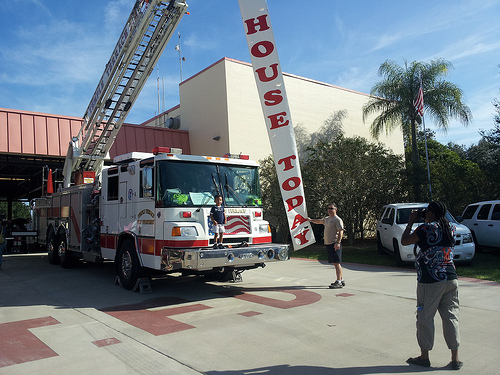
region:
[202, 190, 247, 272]
little boy standing on a truck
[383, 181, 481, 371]
a woman taking a picture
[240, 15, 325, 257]
a large white and red sign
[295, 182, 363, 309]
a man standing by the sign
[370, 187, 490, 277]
a white parked car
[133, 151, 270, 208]
the windshield of a truck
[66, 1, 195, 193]
ladder coming out of the truck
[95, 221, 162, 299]
a tire secured in place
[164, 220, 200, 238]
headlight on a truck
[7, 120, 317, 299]
a red and white firetruck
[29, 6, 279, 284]
a white and red fire hydrant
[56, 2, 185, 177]
a retractable fire ladder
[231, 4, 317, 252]
sign that reads HOUSE TODAY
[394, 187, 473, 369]
a woman taking photograph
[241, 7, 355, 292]
man holding large sign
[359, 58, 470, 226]
a large palm tree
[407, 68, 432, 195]
a waving American flag on pole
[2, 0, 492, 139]
a cloudy blue sky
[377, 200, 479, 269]
a parked white SUV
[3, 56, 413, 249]
large fire house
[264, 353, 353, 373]
shadow on the ground.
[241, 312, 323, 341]
driveway made of concrete.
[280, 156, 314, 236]
red lettering on sign.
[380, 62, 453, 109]
leaves on the tree.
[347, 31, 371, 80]
clouds in the sky.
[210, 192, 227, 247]
kid standing on truck.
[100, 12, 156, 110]
ladder on the truck.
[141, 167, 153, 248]
door of the truck.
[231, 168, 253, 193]
windshield of the truck.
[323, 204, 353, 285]
man standing near the banner.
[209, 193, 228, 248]
a young boy standing on the bumper of a fire truck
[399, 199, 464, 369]
the mother of the boy taking a picture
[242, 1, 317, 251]
a large sign that reads "House Today"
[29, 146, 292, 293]
a white and red fire truck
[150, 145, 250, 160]
lights on the top of the fire truck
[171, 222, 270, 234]
two headlights on the front of the fire truck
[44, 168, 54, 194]
an orange cone on the right side of the fire truck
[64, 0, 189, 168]
a ladder extended on the fire truck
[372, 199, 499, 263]
two white cars parked on the grass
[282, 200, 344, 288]
a man standing beside the House Today sign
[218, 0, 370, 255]
big red and white sign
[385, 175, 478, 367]
woman taking a picture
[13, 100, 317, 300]
red and white firetruck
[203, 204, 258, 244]
image of an american flag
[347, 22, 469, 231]
tall palm tree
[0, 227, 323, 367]
big painted letters on cement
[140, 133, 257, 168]
set of red and white signal lights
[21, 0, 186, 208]
long firetruck ladder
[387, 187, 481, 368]
dark colored woman with dreads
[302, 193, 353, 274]
man in beige t-shirt